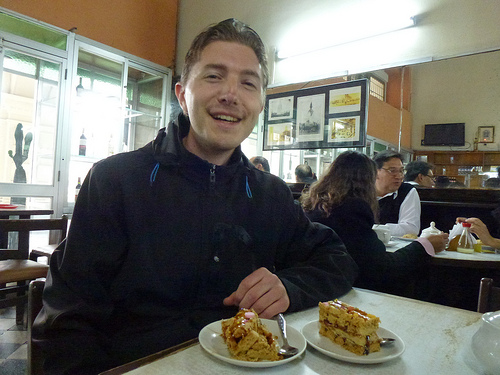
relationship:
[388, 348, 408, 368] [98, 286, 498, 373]
plate on table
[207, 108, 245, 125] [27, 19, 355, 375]
mouth of person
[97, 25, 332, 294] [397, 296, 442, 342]
person sitting at table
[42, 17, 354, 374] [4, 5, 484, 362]
people sitting in diner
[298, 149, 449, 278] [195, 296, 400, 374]
people enjoying their meal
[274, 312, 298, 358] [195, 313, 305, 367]
spoon on plate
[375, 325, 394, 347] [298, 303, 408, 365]
silver spoon on plate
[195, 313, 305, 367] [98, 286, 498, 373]
plate on table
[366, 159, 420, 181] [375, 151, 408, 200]
glasses are on man's head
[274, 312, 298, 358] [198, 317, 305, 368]
spoon on plate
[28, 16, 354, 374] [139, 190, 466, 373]
man sitting at table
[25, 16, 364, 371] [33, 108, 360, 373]
man wearing jacket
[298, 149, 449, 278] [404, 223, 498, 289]
people sitting at table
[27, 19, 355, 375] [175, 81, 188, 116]
person has ear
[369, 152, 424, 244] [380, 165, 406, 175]
person wearing glasses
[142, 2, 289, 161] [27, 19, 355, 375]
head of person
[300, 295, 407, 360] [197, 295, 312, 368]
food getting some food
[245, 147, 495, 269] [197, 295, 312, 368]
people getting some food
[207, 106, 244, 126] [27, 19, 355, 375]
smile of a person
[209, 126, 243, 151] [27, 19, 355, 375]
jaw of a person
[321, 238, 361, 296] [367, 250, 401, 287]
elbow of a elbow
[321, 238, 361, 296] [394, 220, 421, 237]
elbow of a elbow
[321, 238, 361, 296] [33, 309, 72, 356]
elbow of a elbow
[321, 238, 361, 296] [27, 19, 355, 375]
elbow of a person